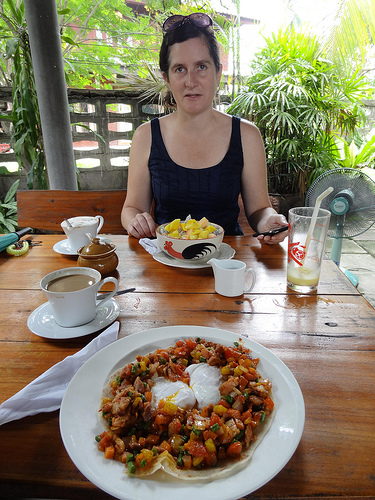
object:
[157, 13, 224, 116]
head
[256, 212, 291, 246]
hand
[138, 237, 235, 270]
plate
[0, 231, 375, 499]
table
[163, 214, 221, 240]
food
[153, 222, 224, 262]
bowl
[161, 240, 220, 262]
chicken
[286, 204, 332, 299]
glass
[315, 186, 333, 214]
straw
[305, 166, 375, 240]
fan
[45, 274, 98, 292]
coffee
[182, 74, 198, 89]
nose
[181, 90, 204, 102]
mouth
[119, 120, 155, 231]
arm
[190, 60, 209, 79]
eye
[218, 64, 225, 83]
ear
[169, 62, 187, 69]
eyebrow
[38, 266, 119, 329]
cup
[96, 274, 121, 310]
handle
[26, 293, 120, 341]
saucer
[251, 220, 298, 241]
phone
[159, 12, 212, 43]
glasses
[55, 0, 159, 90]
plants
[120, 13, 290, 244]
person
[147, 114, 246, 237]
shirt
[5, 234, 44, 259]
keys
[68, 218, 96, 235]
sour cream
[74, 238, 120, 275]
sugar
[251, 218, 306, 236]
cell phone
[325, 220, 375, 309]
floor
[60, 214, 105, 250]
pitcher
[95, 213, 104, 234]
foam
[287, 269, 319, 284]
juice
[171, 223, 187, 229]
eggs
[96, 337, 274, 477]
tortilla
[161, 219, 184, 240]
fruit